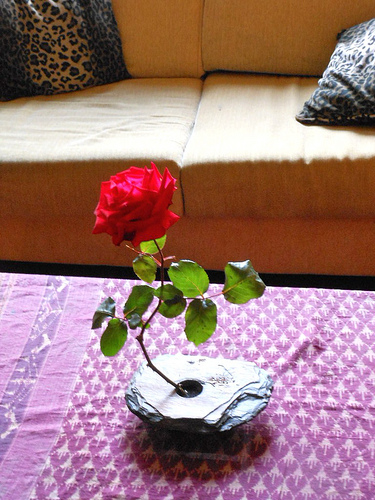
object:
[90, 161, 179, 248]
rose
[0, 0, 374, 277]
couch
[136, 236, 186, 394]
stem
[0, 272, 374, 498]
cloth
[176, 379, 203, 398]
hole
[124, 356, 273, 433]
rock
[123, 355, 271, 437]
vase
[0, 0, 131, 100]
pillow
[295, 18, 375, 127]
pillow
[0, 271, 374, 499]
cover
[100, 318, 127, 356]
leaf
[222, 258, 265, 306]
leaf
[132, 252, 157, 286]
leaf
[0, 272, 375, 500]
table